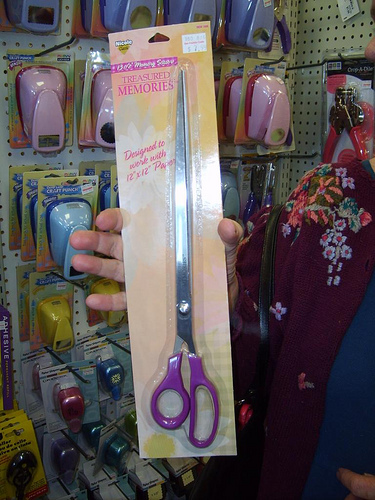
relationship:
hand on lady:
[67, 207, 244, 311] [67, 162, 374, 500]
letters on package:
[116, 72, 177, 95] [102, 19, 241, 457]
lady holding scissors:
[276, 109, 366, 398] [106, 25, 233, 447]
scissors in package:
[148, 61, 241, 448] [105, 21, 237, 458]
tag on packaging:
[177, 30, 217, 60] [95, 17, 250, 466]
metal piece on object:
[177, 298, 190, 314] [150, 67, 219, 447]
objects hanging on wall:
[3, 3, 301, 499] [7, 12, 352, 483]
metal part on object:
[329, 88, 362, 126] [322, 63, 363, 160]